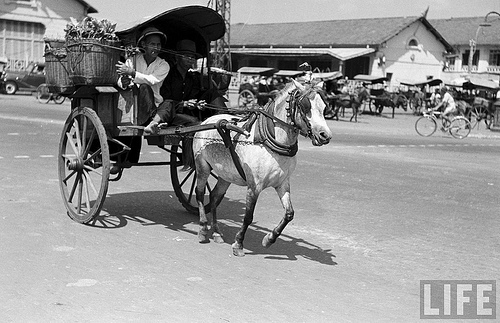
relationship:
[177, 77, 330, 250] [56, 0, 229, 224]
horse pulling carriage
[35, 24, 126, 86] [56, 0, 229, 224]
basket on carriage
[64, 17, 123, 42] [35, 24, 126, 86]
plants in basket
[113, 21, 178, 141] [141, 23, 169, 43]
man has hat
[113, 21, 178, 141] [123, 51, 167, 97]
man wearing white shirt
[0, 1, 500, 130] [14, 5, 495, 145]
carriages in background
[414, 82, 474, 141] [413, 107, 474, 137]
person riding bicycle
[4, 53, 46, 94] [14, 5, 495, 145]
car in background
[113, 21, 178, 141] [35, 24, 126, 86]
man holding baskets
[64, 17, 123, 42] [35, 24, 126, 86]
plants in baskets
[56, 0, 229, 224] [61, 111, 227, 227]
carriage has wheels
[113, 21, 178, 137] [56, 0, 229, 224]
man in carriage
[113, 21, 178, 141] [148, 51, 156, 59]
man has cigarette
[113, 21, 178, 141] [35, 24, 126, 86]
man holds one basket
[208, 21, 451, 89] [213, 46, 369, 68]
building has awning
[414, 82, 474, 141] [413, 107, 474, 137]
person rides bicycle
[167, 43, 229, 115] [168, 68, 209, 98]
man wearing shirt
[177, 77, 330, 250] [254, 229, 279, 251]
horse has hoof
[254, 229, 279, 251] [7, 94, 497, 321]
hoof off road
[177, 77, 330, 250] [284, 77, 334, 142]
horse has head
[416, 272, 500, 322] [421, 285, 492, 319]
life in letters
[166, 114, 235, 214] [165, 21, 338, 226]
wheel on right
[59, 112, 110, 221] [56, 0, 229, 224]
left wheel of carriage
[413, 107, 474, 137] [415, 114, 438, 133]
bicycle has front wheel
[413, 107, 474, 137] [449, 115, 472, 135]
bicycle has back wheel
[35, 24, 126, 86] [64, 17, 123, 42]
basket has plants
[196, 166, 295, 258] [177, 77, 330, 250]
legs on horse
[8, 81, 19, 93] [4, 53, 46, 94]
tire on car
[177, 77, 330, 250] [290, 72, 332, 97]
horse has ears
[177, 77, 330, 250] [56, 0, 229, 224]
horse pulling wagon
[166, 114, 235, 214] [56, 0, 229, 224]
wheel on carriage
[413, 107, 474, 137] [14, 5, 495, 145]
bicycle in background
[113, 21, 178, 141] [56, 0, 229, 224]
man in carriage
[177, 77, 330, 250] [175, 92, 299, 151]
horse has harness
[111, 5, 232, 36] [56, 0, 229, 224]
roof on carriage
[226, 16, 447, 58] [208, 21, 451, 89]
roof on building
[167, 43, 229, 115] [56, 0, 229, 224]
man in carriage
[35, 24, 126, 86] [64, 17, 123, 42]
basket of plants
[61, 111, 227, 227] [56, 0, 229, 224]
wheels on carriage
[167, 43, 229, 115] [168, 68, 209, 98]
man has shirt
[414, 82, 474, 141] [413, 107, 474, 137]
person on bicycle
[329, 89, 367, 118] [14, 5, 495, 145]
horse in background